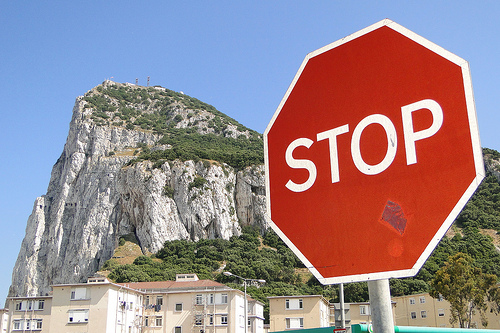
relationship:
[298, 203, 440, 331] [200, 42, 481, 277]
pole holding up stop sign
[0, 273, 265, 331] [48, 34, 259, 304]
building below formation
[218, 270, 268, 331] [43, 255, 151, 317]
street lamp in front of houses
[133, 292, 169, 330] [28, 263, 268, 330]
windows on beige houses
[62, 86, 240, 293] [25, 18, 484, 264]
formation in background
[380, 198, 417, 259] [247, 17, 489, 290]
smudge on sign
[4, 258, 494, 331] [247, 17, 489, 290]
building behind sign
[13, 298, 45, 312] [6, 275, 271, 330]
balconies outside sides of building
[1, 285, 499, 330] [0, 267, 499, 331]
windows on buildings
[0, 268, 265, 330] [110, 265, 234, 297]
building has roof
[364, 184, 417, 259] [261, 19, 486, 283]
paint peeling off sign